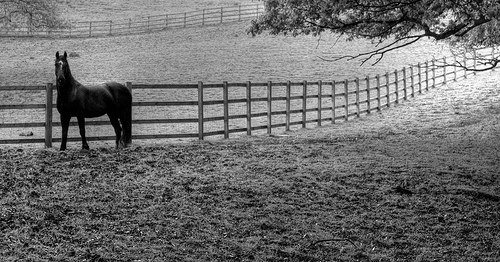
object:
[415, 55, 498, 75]
limbs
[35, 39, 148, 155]
horse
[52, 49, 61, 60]
ear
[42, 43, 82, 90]
head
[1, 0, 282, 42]
fence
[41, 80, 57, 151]
post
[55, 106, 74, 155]
leg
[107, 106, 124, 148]
leg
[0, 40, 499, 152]
fence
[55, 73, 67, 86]
nose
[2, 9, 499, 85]
field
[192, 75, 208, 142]
post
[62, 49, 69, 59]
ear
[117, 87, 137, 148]
tail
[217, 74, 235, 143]
post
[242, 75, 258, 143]
post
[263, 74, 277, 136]
post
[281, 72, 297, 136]
post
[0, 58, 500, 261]
grass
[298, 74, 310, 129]
post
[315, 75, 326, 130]
post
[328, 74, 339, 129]
post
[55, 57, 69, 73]
spot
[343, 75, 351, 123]
post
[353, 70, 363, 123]
post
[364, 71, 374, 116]
post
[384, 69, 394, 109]
post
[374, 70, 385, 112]
post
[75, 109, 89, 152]
leg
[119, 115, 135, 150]
leg